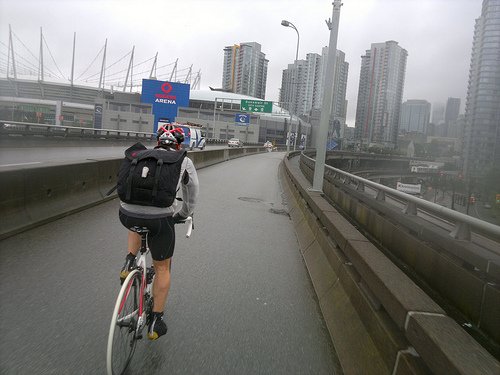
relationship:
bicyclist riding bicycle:
[106, 117, 210, 344] [92, 209, 197, 368]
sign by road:
[137, 74, 192, 124] [226, 150, 286, 315]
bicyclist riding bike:
[106, 117, 210, 344] [117, 222, 156, 367]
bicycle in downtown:
[92, 209, 197, 368] [5, 2, 495, 208]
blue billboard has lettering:
[136, 78, 192, 140] [151, 90, 179, 105]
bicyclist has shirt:
[96, 208, 197, 373] [118, 142, 188, 213]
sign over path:
[238, 91, 276, 117] [2, 144, 348, 374]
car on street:
[214, 126, 253, 152] [0, 143, 231, 170]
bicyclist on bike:
[106, 117, 210, 344] [105, 208, 195, 373]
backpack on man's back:
[114, 142, 192, 209] [118, 133, 193, 234]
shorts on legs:
[119, 212, 174, 259] [123, 230, 173, 333]